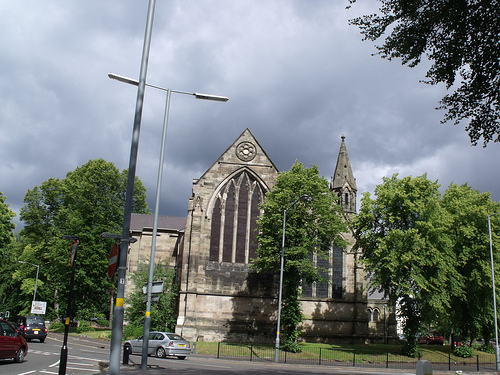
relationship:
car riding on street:
[125, 332, 191, 360] [0, 332, 500, 374]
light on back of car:
[192, 344, 197, 351] [125, 332, 191, 360]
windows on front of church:
[208, 168, 271, 267] [130, 129, 417, 345]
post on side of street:
[272, 206, 298, 363] [0, 332, 500, 374]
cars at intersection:
[2, 318, 189, 364] [2, 327, 111, 374]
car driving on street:
[125, 332, 191, 360] [0, 332, 500, 374]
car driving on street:
[0, 317, 28, 363] [0, 332, 500, 374]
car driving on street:
[14, 314, 46, 342] [0, 332, 500, 374]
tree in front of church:
[258, 160, 346, 355] [130, 129, 417, 345]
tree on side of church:
[24, 160, 148, 327] [130, 129, 417, 345]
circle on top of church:
[236, 140, 255, 163] [130, 129, 417, 345]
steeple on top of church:
[330, 132, 356, 189] [130, 129, 417, 345]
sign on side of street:
[105, 242, 120, 276] [0, 332, 500, 374]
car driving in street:
[0, 317, 28, 363] [0, 332, 500, 374]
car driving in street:
[125, 332, 191, 360] [0, 332, 500, 374]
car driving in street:
[14, 314, 46, 342] [0, 332, 500, 374]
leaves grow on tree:
[347, 3, 499, 139] [258, 160, 346, 355]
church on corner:
[130, 129, 417, 345] [58, 314, 499, 358]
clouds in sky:
[0, 10, 459, 215] [0, 0, 499, 229]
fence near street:
[195, 343, 499, 371] [0, 332, 500, 374]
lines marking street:
[20, 352, 109, 374] [0, 332, 500, 374]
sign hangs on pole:
[69, 240, 82, 260] [59, 240, 82, 375]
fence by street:
[195, 343, 499, 371] [0, 332, 500, 374]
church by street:
[130, 129, 417, 345] [0, 332, 500, 374]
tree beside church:
[24, 160, 148, 327] [130, 129, 417, 345]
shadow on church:
[223, 272, 373, 343] [130, 129, 417, 345]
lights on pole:
[105, 69, 234, 103] [105, 72, 228, 368]